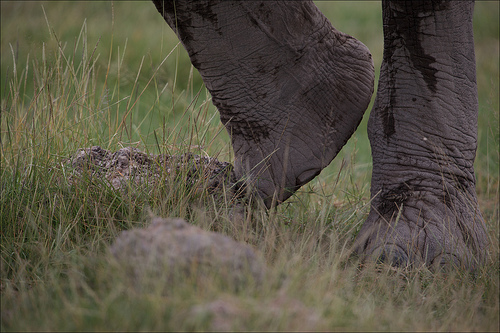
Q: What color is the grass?
A: Green.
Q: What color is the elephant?
A: Gray.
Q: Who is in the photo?
A: An elephant.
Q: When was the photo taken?
A: Daytime.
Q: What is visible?
A: Feet.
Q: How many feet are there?
A: Two.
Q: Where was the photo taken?
A: In a zoo.